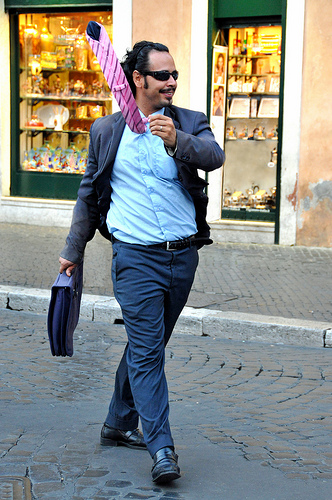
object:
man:
[58, 39, 228, 484]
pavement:
[0, 310, 332, 499]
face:
[141, 45, 178, 107]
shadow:
[157, 474, 180, 497]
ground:
[0, 222, 332, 500]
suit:
[59, 104, 225, 461]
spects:
[136, 65, 179, 82]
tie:
[85, 19, 151, 135]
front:
[154, 456, 180, 478]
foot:
[150, 445, 182, 484]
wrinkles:
[147, 414, 168, 445]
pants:
[101, 241, 199, 457]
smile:
[159, 87, 176, 99]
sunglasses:
[139, 67, 179, 82]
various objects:
[36, 102, 70, 131]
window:
[15, 10, 111, 176]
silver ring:
[159, 125, 163, 132]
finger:
[150, 125, 166, 133]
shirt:
[105, 107, 198, 251]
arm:
[175, 108, 226, 174]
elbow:
[211, 143, 226, 173]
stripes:
[101, 43, 111, 76]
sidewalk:
[0, 222, 332, 347]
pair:
[141, 68, 180, 83]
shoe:
[150, 446, 182, 484]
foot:
[98, 421, 149, 452]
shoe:
[99, 420, 147, 450]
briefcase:
[46, 261, 84, 358]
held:
[56, 254, 77, 277]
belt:
[151, 232, 213, 254]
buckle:
[166, 239, 178, 252]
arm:
[59, 116, 97, 259]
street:
[0, 307, 332, 499]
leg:
[118, 285, 175, 456]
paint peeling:
[286, 171, 300, 214]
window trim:
[206, 0, 287, 245]